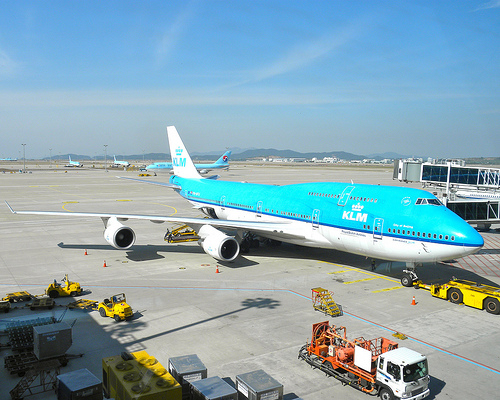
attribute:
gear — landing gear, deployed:
[395, 262, 423, 286]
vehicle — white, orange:
[294, 314, 438, 399]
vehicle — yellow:
[411, 276, 499, 314]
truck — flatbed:
[299, 323, 432, 398]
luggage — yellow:
[417, 271, 499, 313]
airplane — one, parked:
[64, 154, 81, 168]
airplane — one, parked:
[111, 154, 129, 167]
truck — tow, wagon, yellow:
[101, 293, 129, 319]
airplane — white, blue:
[142, 147, 470, 307]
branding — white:
[340, 196, 375, 231]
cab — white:
[375, 346, 433, 398]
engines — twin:
[99, 216, 244, 264]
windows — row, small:
[379, 227, 465, 248]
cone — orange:
[407, 289, 419, 308]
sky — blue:
[3, 1, 499, 171]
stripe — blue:
[184, 196, 486, 250]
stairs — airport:
[316, 285, 343, 320]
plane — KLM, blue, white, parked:
[4, 124, 484, 286]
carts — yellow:
[415, 276, 499, 315]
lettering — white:
[335, 205, 372, 225]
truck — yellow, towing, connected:
[412, 276, 497, 313]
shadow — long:
[111, 297, 283, 348]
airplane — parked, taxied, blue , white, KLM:
[0, 120, 490, 282]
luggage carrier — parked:
[402, 273, 498, 314]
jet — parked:
[144, 178, 497, 255]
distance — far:
[34, 123, 497, 185]